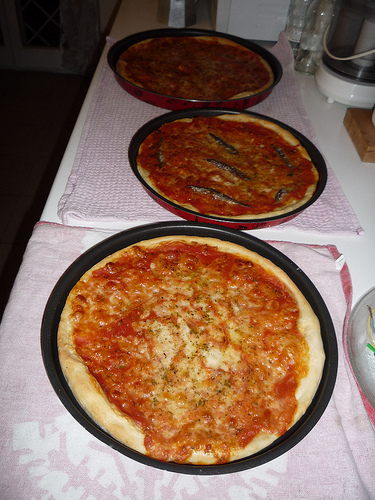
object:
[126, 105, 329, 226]
pizza pan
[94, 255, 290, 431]
melted cheese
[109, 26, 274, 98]
pizzas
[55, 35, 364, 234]
dish towel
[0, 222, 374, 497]
dish towel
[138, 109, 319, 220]
pizza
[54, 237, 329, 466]
cheese pizza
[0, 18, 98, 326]
floor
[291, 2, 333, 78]
bottle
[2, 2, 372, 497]
table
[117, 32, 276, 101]
pizza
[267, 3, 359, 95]
shakers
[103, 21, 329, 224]
two pizzas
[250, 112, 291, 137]
crust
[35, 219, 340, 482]
black dish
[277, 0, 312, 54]
glass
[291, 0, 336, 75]
glass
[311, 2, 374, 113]
food processor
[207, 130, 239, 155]
anchovies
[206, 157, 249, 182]
anchovies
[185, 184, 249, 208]
anchovies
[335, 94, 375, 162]
block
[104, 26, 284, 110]
pan